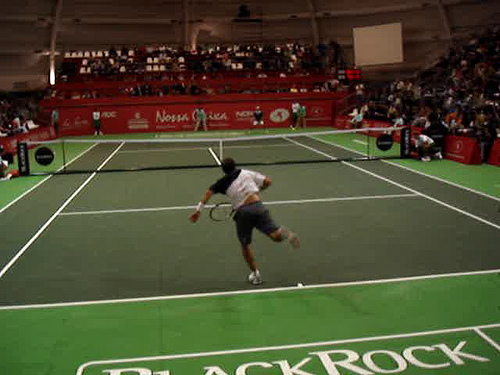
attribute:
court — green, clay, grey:
[61, 132, 495, 278]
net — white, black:
[61, 135, 360, 181]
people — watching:
[98, 49, 316, 95]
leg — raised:
[266, 228, 302, 251]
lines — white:
[52, 160, 460, 212]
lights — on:
[48, 1, 250, 29]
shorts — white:
[250, 119, 273, 129]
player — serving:
[208, 155, 295, 291]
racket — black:
[212, 186, 265, 223]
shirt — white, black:
[214, 165, 273, 208]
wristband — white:
[191, 200, 210, 218]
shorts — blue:
[235, 189, 272, 254]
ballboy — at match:
[406, 136, 445, 166]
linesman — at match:
[291, 105, 306, 131]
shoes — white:
[248, 227, 288, 285]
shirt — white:
[415, 137, 428, 146]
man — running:
[349, 106, 372, 135]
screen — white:
[347, 20, 406, 71]